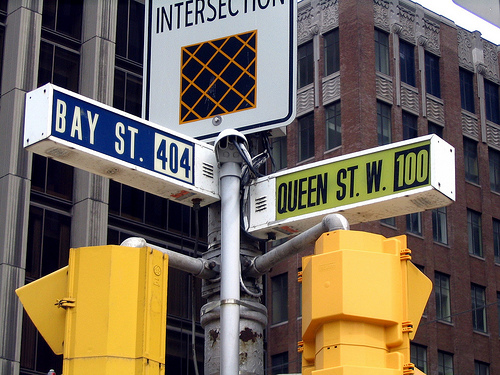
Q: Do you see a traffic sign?
A: Yes, there is a traffic sign.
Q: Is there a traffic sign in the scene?
A: Yes, there is a traffic sign.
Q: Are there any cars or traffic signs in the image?
A: Yes, there is a traffic sign.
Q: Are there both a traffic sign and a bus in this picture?
A: No, there is a traffic sign but no buses.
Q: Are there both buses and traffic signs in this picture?
A: No, there is a traffic sign but no buses.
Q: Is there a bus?
A: No, there are no buses.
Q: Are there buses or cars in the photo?
A: No, there are no buses or cars.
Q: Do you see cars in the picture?
A: No, there are no cars.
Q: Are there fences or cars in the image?
A: No, there are no cars or fences.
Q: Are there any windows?
A: Yes, there is a window.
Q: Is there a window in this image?
A: Yes, there is a window.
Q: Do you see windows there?
A: Yes, there is a window.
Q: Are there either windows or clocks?
A: Yes, there is a window.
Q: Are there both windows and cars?
A: No, there is a window but no cars.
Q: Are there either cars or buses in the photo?
A: No, there are no buses or cars.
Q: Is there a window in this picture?
A: Yes, there is a window.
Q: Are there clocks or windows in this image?
A: Yes, there is a window.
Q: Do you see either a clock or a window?
A: Yes, there is a window.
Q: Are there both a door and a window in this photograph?
A: No, there is a window but no doors.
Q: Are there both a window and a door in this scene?
A: No, there is a window but no doors.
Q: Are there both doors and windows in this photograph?
A: No, there is a window but no doors.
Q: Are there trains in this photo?
A: No, there are no trains.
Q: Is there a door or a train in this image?
A: No, there are no trains or doors.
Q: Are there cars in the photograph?
A: No, there are no cars.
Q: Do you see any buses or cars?
A: No, there are no cars or buses.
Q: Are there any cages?
A: No, there are no cages.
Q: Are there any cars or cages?
A: No, there are no cages or cars.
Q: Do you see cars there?
A: No, there are no cars.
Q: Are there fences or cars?
A: No, there are no cars or fences.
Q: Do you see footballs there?
A: No, there are no footballs.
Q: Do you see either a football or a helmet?
A: No, there are no footballs or helmets.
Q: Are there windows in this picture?
A: Yes, there is a window.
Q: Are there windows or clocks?
A: Yes, there is a window.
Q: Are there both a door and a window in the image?
A: No, there is a window but no doors.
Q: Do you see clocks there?
A: No, there are no clocks.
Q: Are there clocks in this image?
A: No, there are no clocks.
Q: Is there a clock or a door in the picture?
A: No, there are no clocks or doors.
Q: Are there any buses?
A: No, there are no buses.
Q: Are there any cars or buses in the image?
A: No, there are no buses or cars.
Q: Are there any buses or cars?
A: No, there are no buses or cars.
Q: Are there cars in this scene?
A: No, there are no cars.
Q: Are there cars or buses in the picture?
A: No, there are no cars or buses.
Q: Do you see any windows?
A: Yes, there is a window.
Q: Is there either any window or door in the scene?
A: Yes, there is a window.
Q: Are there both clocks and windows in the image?
A: No, there is a window but no clocks.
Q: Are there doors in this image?
A: No, there are no doors.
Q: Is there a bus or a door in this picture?
A: No, there are no doors or buses.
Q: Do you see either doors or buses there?
A: No, there are no doors or buses.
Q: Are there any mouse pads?
A: No, there are no mouse pads.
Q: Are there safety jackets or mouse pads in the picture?
A: No, there are no mouse pads or safety jackets.